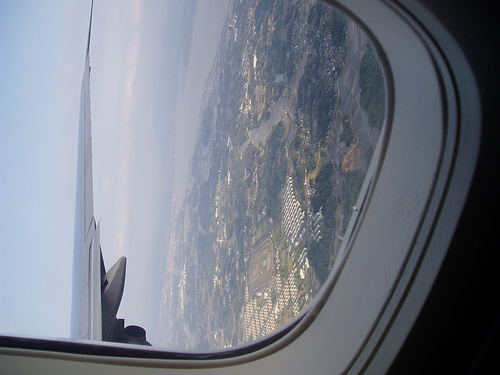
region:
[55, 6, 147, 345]
long, thin wing of the plane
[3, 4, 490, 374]
window of an airplane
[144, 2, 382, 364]
land can be seen from the window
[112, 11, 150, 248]
thin white cloud in the sky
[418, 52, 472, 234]
lines on the window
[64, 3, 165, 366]
wing can be seen from the window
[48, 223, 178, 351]
jet engine underneat the wing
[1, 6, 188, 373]
bright blue sky that looks a little cloudy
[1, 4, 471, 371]
small window on an airplane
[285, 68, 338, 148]
patch of dark green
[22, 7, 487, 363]
airplane window in back of wing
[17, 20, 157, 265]
hazy blue sky with long clouds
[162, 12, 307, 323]
the ground appearing upright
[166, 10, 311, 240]
water and waterways curving through land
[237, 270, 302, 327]
rows of white crisscrossing structures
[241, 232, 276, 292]
rectangular form within a rectangle border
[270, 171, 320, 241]
white cylinders jutting out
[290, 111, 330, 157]
dots of buildings surrounded by greenery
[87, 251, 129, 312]
pointy protrusion in back of wing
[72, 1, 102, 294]
narrowing of wing to a straight line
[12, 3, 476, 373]
the window of the plane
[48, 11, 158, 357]
the wing of the plane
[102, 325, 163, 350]
the engine under the wing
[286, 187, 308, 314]
the houses on the ground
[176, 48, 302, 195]
the meandering river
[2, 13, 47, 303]
the clear blue sky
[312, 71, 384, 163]
the farms on the ground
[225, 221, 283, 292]
the sports field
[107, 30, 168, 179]
the clouds in the sky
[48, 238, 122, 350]
the forward flap of the wing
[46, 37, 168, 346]
airplane wing out the window of the plane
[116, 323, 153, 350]
engine under the wing of the plane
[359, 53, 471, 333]
edge of a window on a plane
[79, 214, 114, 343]
flap on the wing of a plane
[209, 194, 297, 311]
city out the window of the plane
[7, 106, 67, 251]
sky outside the window of the plane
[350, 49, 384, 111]
tops of trees on the ground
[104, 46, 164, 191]
clouds in the sky beyond the wing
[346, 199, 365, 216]
rivet on the outside of the window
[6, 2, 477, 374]
window in an airplane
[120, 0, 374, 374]
view of the ground from an airplane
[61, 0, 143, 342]
wing of an airplane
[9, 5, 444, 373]
an airplane window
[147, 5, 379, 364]
trees on the ground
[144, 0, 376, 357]
buildings on the ground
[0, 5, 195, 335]
blue sky above the plane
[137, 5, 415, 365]
dirt on the ground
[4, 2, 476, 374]
white window siding on the plane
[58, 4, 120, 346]
white plane wing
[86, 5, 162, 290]
white cloud in the sky